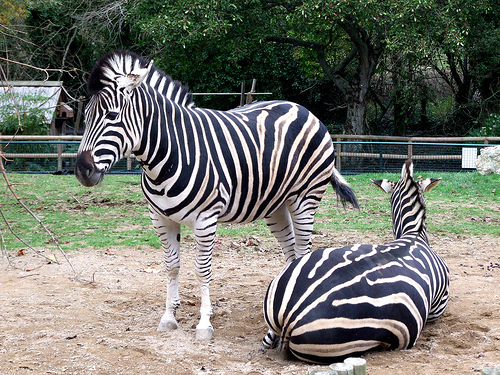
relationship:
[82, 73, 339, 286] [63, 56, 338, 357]
black stripe on zebra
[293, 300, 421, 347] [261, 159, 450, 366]
stripe on zebra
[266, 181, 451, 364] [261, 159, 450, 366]
black stripe on zebra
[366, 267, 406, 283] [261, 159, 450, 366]
stripe on zebra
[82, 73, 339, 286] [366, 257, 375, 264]
black stripe on stripe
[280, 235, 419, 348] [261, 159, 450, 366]
black stripe on zebra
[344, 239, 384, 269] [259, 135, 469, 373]
stripe on zebra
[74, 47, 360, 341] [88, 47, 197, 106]
zebra has a mane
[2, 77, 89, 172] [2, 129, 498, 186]
building in background behind a fence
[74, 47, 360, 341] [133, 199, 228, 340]
zebra has two front legs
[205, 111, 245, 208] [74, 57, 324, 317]
stripe on zebra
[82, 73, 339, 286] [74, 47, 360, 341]
black stripe on zebra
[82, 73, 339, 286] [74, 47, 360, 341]
black stripe on a zebra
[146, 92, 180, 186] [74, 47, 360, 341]
black stripe on zebra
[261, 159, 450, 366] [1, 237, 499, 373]
zebra laying in dirt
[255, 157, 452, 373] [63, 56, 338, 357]
zebra next to zebra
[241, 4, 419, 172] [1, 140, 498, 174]
tree beyond fence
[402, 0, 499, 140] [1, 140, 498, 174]
tree beyond fence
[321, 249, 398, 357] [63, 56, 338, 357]
stripes on zebra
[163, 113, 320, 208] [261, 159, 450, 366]
stripes on zebra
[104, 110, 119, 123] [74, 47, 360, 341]
eye on zebra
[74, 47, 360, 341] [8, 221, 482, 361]
zebra on ground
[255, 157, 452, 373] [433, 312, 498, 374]
zebra on ground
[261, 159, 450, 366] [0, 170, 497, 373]
zebra on ground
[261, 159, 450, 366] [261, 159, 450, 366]
zebra next to zebra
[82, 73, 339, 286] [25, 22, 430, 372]
black stripe on zebra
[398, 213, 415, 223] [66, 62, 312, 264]
stripe on zebra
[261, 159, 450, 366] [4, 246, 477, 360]
zebra sitting in dirt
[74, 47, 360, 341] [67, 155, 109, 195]
zebra has nose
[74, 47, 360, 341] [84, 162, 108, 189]
zebra has mouth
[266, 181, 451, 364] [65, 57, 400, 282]
black stripe on zebra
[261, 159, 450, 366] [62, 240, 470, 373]
zebra standing in dirt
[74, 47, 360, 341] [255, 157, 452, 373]
zebra standing next to zebra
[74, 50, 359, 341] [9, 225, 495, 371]
zebra on ground